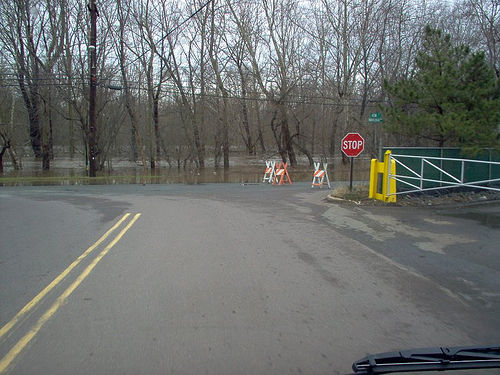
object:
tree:
[373, 22, 489, 154]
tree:
[1, 0, 74, 173]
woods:
[85, 156, 100, 181]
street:
[2, 189, 499, 369]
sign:
[366, 112, 387, 122]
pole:
[372, 123, 378, 164]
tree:
[315, 0, 365, 163]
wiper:
[353, 344, 498, 373]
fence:
[375, 142, 497, 184]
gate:
[382, 152, 497, 199]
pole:
[78, 2, 104, 177]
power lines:
[6, 64, 391, 109]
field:
[198, 147, 256, 178]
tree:
[137, 1, 167, 170]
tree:
[229, 0, 312, 167]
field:
[0, 0, 496, 178]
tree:
[283, 11, 499, 153]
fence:
[203, 122, 493, 219]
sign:
[337, 130, 368, 160]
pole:
[348, 154, 358, 188]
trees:
[84, 0, 106, 180]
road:
[146, 169, 363, 362]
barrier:
[309, 162, 330, 188]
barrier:
[356, 141, 401, 208]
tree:
[161, 4, 251, 165]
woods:
[281, 132, 297, 159]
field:
[238, 12, 499, 169]